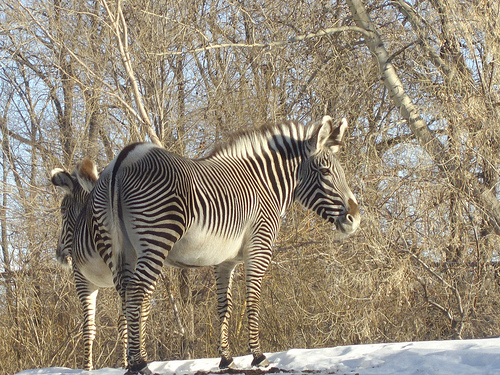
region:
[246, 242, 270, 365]
this is a zebra's leg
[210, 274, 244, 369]
this is a zebra's leg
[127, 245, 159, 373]
this is a zebra's leg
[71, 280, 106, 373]
this is a zebra's leg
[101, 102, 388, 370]
this is a zebra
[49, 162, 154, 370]
this is a zebra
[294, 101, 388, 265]
this is a zebra's head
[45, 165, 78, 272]
this is a zebra's head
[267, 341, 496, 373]
this is snow covered ground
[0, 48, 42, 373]
this is a tree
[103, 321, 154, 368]
Two zebras looking out at the snow.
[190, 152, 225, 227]
Two zebras looking out at the snow.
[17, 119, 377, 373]
these are the zebras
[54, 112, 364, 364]
they are motionless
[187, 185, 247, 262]
the belly is fat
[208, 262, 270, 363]
these are the legs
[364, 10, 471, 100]
this is the tree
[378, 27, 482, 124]
the tree is branchy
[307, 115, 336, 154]
this is the ear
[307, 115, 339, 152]
the ear is big in size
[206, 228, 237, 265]
part of a tummy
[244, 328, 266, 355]
part of a hioof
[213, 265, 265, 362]
The front legs of the zebra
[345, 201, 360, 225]
The nose of the zebra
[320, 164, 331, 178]
The right eye of the zebra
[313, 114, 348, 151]
The ears of the zebra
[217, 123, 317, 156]
The mane of the zebra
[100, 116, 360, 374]
A zebra standing in the snow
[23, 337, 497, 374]
Snow beneath the zebras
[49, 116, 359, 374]
Two zebras by the trees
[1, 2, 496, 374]
Trees near the zebras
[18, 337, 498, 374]
Snow on the ground